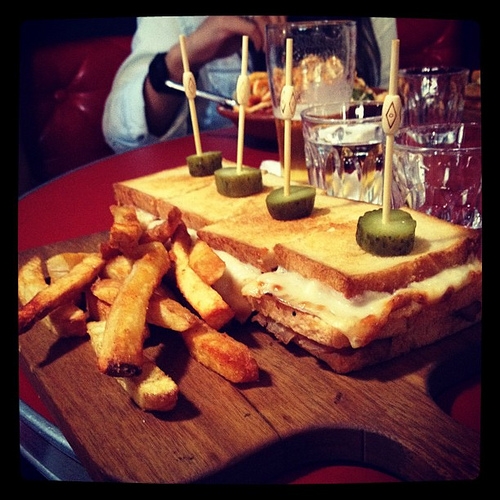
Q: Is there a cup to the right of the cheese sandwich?
A: Yes, there are cups to the right of the sandwich.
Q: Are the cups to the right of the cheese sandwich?
A: Yes, the cups are to the right of the sandwich.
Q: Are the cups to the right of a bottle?
A: No, the cups are to the right of the sandwich.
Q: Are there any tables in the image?
A: Yes, there is a table.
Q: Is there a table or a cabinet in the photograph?
A: Yes, there is a table.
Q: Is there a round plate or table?
A: Yes, there is a round table.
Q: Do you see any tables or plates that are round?
A: Yes, the table is round.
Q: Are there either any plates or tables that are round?
A: Yes, the table is round.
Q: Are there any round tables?
A: Yes, there is a round table.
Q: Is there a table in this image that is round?
A: Yes, there is a table that is round.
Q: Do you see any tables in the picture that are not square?
A: Yes, there is a round table.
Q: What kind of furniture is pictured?
A: The furniture is a table.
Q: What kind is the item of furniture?
A: The piece of furniture is a table.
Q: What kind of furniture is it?
A: The piece of furniture is a table.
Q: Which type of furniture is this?
A: This is a table.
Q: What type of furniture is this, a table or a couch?
A: This is a table.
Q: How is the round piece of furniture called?
A: The piece of furniture is a table.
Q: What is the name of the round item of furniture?
A: The piece of furniture is a table.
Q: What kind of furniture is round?
A: The furniture is a table.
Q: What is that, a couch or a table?
A: That is a table.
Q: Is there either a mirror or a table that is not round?
A: No, there is a table but it is round.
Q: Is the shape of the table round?
A: Yes, the table is round.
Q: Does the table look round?
A: Yes, the table is round.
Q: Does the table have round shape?
A: Yes, the table is round.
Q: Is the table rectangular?
A: No, the table is round.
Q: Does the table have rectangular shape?
A: No, the table is round.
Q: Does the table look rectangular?
A: No, the table is round.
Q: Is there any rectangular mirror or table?
A: No, there is a table but it is round.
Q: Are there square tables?
A: No, there is a table but it is round.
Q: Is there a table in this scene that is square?
A: No, there is a table but it is round.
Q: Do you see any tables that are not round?
A: No, there is a table but it is round.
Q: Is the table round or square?
A: The table is round.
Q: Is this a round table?
A: Yes, this is a round table.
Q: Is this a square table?
A: No, this is a round table.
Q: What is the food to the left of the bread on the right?
A: The food is fries.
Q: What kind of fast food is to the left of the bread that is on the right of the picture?
A: The food is fries.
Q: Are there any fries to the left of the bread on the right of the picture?
A: Yes, there are fries to the left of the bread.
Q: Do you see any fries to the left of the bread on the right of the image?
A: Yes, there are fries to the left of the bread.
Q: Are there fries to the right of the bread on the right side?
A: No, the fries are to the left of the bread.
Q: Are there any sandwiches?
A: Yes, there is a sandwich.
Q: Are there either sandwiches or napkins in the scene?
A: Yes, there is a sandwich.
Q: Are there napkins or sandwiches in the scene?
A: Yes, there is a sandwich.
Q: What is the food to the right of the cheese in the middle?
A: The food is a sandwich.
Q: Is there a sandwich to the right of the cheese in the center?
A: Yes, there is a sandwich to the right of the cheese.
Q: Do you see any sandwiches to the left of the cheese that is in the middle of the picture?
A: No, the sandwich is to the right of the cheese.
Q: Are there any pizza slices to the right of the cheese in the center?
A: No, there is a sandwich to the right of the cheese.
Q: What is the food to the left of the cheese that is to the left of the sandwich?
A: The food is fries.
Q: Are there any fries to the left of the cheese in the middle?
A: Yes, there are fries to the left of the cheese.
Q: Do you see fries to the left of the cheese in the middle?
A: Yes, there are fries to the left of the cheese.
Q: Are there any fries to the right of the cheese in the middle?
A: No, the fries are to the left of the cheese.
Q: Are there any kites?
A: No, there are no kites.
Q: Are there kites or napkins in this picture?
A: No, there are no kites or napkins.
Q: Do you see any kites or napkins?
A: No, there are no kites or napkins.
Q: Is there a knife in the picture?
A: No, there are no knives.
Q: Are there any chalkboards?
A: No, there are no chalkboards.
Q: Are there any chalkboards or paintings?
A: No, there are no chalkboards or paintings.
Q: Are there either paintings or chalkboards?
A: No, there are no chalkboards or paintings.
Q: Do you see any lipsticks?
A: No, there are no lipsticks.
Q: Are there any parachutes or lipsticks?
A: No, there are no lipsticks or parachutes.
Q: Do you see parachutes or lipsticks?
A: No, there are no lipsticks or parachutes.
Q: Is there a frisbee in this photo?
A: No, there are no frisbees.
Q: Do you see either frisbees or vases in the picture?
A: No, there are no frisbees or vases.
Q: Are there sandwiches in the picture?
A: Yes, there is a sandwich.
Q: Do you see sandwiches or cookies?
A: Yes, there is a sandwich.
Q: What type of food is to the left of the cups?
A: The food is a sandwich.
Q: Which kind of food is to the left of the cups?
A: The food is a sandwich.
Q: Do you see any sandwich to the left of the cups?
A: Yes, there is a sandwich to the left of the cups.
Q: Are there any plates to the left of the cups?
A: No, there is a sandwich to the left of the cups.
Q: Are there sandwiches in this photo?
A: Yes, there is a sandwich.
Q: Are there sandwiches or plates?
A: Yes, there is a sandwich.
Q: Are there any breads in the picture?
A: Yes, there is a bread.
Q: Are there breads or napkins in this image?
A: Yes, there is a bread.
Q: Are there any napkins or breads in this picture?
A: Yes, there is a bread.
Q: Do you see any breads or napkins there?
A: Yes, there is a bread.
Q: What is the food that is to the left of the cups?
A: The food is a bread.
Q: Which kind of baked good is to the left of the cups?
A: The food is a bread.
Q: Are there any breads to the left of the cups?
A: Yes, there is a bread to the left of the cups.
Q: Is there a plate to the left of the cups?
A: No, there is a bread to the left of the cups.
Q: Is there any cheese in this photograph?
A: Yes, there is cheese.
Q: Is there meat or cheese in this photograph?
A: Yes, there is cheese.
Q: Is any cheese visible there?
A: Yes, there is cheese.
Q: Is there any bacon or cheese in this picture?
A: Yes, there is cheese.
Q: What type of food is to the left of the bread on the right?
A: The food is cheese.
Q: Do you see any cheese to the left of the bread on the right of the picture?
A: Yes, there is cheese to the left of the bread.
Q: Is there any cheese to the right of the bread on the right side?
A: No, the cheese is to the left of the bread.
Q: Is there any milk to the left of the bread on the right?
A: No, there is cheese to the left of the bread.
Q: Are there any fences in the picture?
A: No, there are no fences.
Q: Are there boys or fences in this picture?
A: No, there are no fences or boys.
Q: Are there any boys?
A: No, there are no boys.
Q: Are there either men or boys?
A: No, there are no boys or men.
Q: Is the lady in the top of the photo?
A: Yes, the lady is in the top of the image.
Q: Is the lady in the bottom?
A: No, the lady is in the top of the image.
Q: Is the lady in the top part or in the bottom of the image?
A: The lady is in the top of the image.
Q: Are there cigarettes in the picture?
A: No, there are no cigarettes.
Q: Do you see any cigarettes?
A: No, there are no cigarettes.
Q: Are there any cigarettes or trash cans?
A: No, there are no cigarettes or trash cans.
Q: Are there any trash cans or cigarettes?
A: No, there are no cigarettes or trash cans.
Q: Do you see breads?
A: Yes, there is a bread.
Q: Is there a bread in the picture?
A: Yes, there is a bread.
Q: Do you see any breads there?
A: Yes, there is a bread.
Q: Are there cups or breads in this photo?
A: Yes, there is a bread.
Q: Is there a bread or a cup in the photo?
A: Yes, there is a bread.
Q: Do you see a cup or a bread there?
A: Yes, there is a bread.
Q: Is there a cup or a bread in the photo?
A: Yes, there is a bread.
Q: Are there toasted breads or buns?
A: Yes, there is a toasted bread.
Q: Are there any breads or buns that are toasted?
A: Yes, the bread is toasted.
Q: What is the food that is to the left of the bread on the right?
A: The food is fries.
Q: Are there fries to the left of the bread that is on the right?
A: Yes, there are fries to the left of the bread.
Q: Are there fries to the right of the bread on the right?
A: No, the fries are to the left of the bread.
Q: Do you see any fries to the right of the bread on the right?
A: No, the fries are to the left of the bread.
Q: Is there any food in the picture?
A: Yes, there is food.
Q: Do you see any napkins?
A: No, there are no napkins.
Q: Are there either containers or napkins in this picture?
A: No, there are no napkins or containers.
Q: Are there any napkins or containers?
A: No, there are no napkins or containers.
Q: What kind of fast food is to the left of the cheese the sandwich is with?
A: The food is fries.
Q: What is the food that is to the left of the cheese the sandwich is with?
A: The food is fries.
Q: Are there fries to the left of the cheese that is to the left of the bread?
A: Yes, there are fries to the left of the cheese.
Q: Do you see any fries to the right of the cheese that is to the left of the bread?
A: No, the fries are to the left of the cheese.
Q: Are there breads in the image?
A: Yes, there is a bread.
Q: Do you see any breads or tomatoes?
A: Yes, there is a bread.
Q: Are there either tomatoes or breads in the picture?
A: Yes, there is a bread.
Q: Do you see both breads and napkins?
A: No, there is a bread but no napkins.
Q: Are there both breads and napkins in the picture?
A: No, there is a bread but no napkins.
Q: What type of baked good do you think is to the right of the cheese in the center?
A: The food is a bread.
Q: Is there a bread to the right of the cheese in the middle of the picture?
A: Yes, there is a bread to the right of the cheese.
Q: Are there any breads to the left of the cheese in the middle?
A: No, the bread is to the right of the cheese.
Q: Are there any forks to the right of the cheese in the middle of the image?
A: No, there is a bread to the right of the cheese.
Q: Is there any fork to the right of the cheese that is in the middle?
A: No, there is a bread to the right of the cheese.